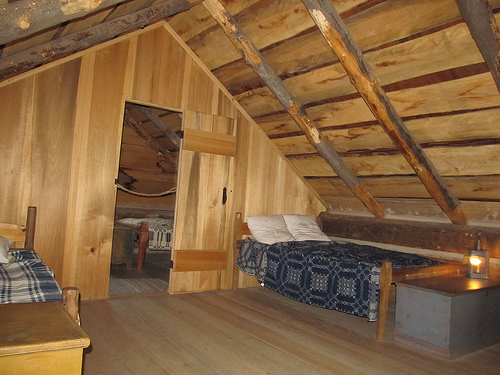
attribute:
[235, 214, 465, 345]
bed — inside, small, wood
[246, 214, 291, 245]
pillow — white, square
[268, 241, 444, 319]
blanket — blue, patterned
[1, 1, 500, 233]
roof — slanted, logs, wood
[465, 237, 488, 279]
light — on, lit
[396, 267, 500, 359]
table — gray, wood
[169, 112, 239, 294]
door — wood, open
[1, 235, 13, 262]
pillow — white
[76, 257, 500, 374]
floor — wood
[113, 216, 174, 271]
bed — pillowless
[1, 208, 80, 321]
bed — wood